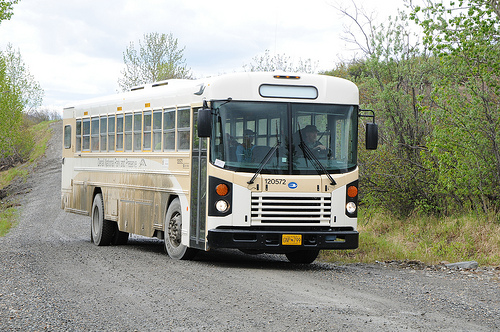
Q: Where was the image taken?
A: It was taken at the road.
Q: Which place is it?
A: It is a road.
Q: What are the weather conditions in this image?
A: It is partly cloudy.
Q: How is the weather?
A: It is partly cloudy.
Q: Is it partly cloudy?
A: Yes, it is partly cloudy.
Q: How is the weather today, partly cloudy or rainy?
A: It is partly cloudy.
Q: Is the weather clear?
A: No, it is partly cloudy.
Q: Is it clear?
A: No, it is partly cloudy.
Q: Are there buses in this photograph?
A: Yes, there is a bus.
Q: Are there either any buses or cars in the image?
A: Yes, there is a bus.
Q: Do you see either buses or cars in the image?
A: Yes, there is a bus.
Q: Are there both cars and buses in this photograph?
A: No, there is a bus but no cars.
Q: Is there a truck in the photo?
A: No, there are no trucks.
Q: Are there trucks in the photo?
A: No, there are no trucks.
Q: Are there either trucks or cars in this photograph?
A: No, there are no trucks or cars.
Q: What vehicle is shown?
A: The vehicle is a bus.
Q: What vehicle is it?
A: The vehicle is a bus.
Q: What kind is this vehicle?
A: That is a bus.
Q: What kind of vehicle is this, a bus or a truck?
A: That is a bus.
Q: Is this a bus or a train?
A: This is a bus.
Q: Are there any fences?
A: No, there are no fences.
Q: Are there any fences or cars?
A: No, there are no fences or cars.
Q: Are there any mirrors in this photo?
A: Yes, there is a mirror.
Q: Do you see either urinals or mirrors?
A: Yes, there is a mirror.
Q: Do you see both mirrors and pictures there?
A: No, there is a mirror but no pictures.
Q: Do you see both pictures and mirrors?
A: No, there is a mirror but no pictures.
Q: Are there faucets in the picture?
A: No, there are no faucets.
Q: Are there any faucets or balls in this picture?
A: No, there are no faucets or balls.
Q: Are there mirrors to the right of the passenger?
A: Yes, there is a mirror to the right of the passenger.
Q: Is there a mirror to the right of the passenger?
A: Yes, there is a mirror to the right of the passenger.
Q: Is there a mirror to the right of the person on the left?
A: Yes, there is a mirror to the right of the passenger.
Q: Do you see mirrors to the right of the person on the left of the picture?
A: Yes, there is a mirror to the right of the passenger.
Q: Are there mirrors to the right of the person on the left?
A: Yes, there is a mirror to the right of the passenger.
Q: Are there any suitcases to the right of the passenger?
A: No, there is a mirror to the right of the passenger.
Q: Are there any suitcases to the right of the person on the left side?
A: No, there is a mirror to the right of the passenger.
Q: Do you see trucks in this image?
A: No, there are no trucks.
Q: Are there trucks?
A: No, there are no trucks.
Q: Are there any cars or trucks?
A: No, there are no trucks or cars.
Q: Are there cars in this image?
A: No, there are no cars.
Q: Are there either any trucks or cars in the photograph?
A: No, there are no cars or trucks.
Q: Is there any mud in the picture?
A: Yes, there is mud.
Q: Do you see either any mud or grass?
A: Yes, there is mud.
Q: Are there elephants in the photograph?
A: No, there are no elephants.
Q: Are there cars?
A: No, there are no cars.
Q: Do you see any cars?
A: No, there are no cars.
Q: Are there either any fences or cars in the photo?
A: No, there are no cars or fences.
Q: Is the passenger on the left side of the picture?
A: Yes, the passenger is on the left of the image.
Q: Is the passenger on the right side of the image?
A: No, the passenger is on the left of the image.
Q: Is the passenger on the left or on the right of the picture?
A: The passenger is on the left of the image.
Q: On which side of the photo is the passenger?
A: The passenger is on the left of the image.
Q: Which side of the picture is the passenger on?
A: The passenger is on the left of the image.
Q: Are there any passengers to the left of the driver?
A: Yes, there is a passenger to the left of the driver.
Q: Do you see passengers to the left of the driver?
A: Yes, there is a passenger to the left of the driver.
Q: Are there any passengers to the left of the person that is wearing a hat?
A: Yes, there is a passenger to the left of the driver.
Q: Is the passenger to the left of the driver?
A: Yes, the passenger is to the left of the driver.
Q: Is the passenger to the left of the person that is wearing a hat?
A: Yes, the passenger is to the left of the driver.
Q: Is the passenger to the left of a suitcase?
A: No, the passenger is to the left of the driver.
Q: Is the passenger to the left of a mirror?
A: Yes, the passenger is to the left of a mirror.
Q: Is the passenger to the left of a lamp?
A: No, the passenger is to the left of a mirror.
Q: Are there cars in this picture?
A: No, there are no cars.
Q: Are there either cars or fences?
A: No, there are no cars or fences.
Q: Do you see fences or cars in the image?
A: No, there are no cars or fences.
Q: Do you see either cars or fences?
A: No, there are no cars or fences.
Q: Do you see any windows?
A: Yes, there is a window.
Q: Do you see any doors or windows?
A: Yes, there is a window.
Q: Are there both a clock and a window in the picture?
A: No, there is a window but no clocks.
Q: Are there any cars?
A: No, there are no cars.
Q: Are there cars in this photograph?
A: No, there are no cars.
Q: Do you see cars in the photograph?
A: No, there are no cars.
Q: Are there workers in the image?
A: No, there are no workers.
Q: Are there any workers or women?
A: No, there are no workers or women.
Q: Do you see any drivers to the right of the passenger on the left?
A: Yes, there is a driver to the right of the passenger.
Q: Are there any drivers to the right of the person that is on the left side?
A: Yes, there is a driver to the right of the passenger.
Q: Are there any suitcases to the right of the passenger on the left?
A: No, there is a driver to the right of the passenger.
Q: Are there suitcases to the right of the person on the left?
A: No, there is a driver to the right of the passenger.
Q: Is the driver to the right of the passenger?
A: Yes, the driver is to the right of the passenger.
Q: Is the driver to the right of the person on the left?
A: Yes, the driver is to the right of the passenger.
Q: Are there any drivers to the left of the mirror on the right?
A: Yes, there is a driver to the left of the mirror.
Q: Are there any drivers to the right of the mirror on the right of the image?
A: No, the driver is to the left of the mirror.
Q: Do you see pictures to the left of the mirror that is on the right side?
A: No, there is a driver to the left of the mirror.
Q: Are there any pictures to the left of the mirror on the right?
A: No, there is a driver to the left of the mirror.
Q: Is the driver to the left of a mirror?
A: Yes, the driver is to the left of a mirror.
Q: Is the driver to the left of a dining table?
A: No, the driver is to the left of a mirror.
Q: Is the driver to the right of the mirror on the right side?
A: No, the driver is to the left of the mirror.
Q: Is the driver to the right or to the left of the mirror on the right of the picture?
A: The driver is to the left of the mirror.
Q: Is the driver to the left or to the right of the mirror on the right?
A: The driver is to the left of the mirror.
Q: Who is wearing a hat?
A: The driver is wearing a hat.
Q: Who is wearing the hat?
A: The driver is wearing a hat.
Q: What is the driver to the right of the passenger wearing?
A: The driver is wearing a hat.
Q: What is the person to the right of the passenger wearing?
A: The driver is wearing a hat.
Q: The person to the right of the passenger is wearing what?
A: The driver is wearing a hat.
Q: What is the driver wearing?
A: The driver is wearing a hat.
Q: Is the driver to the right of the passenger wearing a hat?
A: Yes, the driver is wearing a hat.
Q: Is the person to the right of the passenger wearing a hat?
A: Yes, the driver is wearing a hat.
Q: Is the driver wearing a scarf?
A: No, the driver is wearing a hat.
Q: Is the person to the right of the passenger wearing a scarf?
A: No, the driver is wearing a hat.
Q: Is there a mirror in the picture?
A: Yes, there is a mirror.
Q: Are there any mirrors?
A: Yes, there is a mirror.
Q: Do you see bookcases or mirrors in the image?
A: Yes, there is a mirror.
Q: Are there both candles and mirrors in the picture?
A: No, there is a mirror but no candles.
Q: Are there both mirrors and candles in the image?
A: No, there is a mirror but no candles.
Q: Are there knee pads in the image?
A: No, there are no knee pads.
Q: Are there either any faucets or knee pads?
A: No, there are no knee pads or faucets.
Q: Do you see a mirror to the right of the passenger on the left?
A: Yes, there is a mirror to the right of the passenger.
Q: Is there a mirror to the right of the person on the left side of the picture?
A: Yes, there is a mirror to the right of the passenger.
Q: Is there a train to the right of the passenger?
A: No, there is a mirror to the right of the passenger.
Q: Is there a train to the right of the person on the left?
A: No, there is a mirror to the right of the passenger.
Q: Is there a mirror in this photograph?
A: Yes, there is a mirror.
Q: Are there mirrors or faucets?
A: Yes, there is a mirror.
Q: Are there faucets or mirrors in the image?
A: Yes, there is a mirror.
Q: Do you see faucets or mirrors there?
A: Yes, there is a mirror.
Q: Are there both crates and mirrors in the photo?
A: No, there is a mirror but no crates.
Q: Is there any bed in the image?
A: No, there are no beds.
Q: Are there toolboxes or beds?
A: No, there are no beds or toolboxes.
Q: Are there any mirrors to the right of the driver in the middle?
A: Yes, there is a mirror to the right of the driver.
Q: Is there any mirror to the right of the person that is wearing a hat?
A: Yes, there is a mirror to the right of the driver.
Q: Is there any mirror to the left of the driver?
A: No, the mirror is to the right of the driver.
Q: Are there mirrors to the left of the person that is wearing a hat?
A: No, the mirror is to the right of the driver.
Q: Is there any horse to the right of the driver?
A: No, there is a mirror to the right of the driver.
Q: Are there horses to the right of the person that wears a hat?
A: No, there is a mirror to the right of the driver.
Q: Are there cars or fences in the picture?
A: No, there are no cars or fences.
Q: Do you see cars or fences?
A: No, there are no cars or fences.